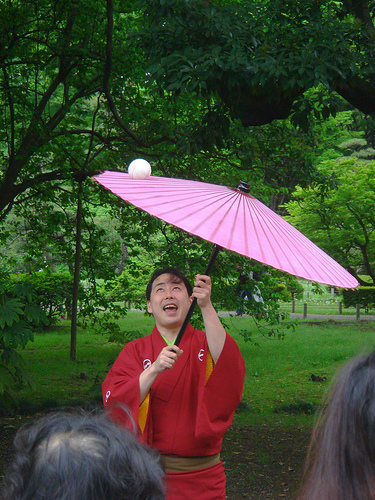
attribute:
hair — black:
[20, 424, 159, 494]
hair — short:
[136, 264, 195, 301]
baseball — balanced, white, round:
[128, 157, 155, 182]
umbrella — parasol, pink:
[94, 168, 361, 364]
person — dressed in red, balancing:
[101, 267, 243, 498]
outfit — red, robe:
[104, 324, 248, 497]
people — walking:
[232, 255, 272, 321]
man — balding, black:
[10, 410, 160, 497]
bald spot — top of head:
[28, 428, 99, 459]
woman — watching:
[304, 348, 374, 499]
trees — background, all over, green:
[1, 1, 373, 292]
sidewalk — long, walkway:
[52, 295, 373, 325]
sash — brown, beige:
[140, 451, 222, 474]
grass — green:
[22, 311, 366, 421]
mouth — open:
[161, 300, 185, 318]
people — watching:
[15, 349, 375, 499]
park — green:
[6, 2, 368, 497]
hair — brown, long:
[306, 356, 368, 499]